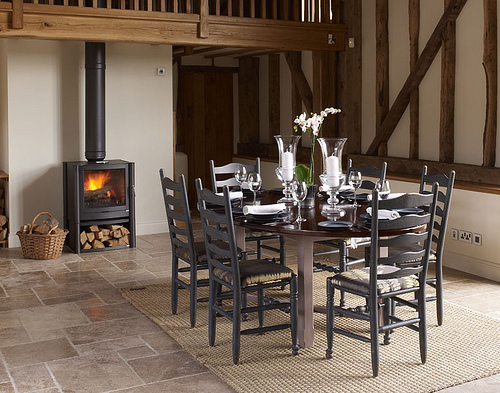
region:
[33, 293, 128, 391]
The floor is tiled.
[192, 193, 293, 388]
The chair is grey.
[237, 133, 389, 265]
The table is set.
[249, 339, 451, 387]
The rug is tan.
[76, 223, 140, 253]
The wood is under the fireplace.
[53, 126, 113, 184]
The fireplace is on.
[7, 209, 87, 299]
The basket is next to the fire place.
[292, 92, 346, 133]
The flower is white.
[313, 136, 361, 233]
The candle is white.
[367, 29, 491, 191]
The panels are white.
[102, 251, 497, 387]
Floor mate with dining room set setting on it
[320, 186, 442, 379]
Dark brown dining room chair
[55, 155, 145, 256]
Wood burning stove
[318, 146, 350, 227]
White candle in candle holder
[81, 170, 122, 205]
Fire in wood burning stove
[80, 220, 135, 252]
Chopped logs for wood burning stove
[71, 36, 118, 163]
Black wood stove pipe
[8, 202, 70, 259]
Basket with chopped logs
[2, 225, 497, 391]
Ceramic tiled floor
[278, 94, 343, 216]
White flowers in a vase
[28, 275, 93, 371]
this is the floor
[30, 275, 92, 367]
the floor is made of tiles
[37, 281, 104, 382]
the floor is slippery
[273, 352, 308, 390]
this is a carpet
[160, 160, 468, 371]
these are six chairs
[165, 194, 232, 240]
the chairs are wooden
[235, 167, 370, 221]
these are several champagne glases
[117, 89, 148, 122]
this is the wall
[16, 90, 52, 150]
the wall is white in color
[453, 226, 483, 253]
this is a socket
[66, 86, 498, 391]
a dinning room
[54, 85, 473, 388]
a dining room with fireplace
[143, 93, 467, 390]
a back chairs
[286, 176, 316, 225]
a wine glass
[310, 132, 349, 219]
a glass candle holder with candle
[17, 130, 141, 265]
a fireplace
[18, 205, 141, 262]
a pile of firewood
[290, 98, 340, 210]
an orchid as a center piece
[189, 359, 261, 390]
a rug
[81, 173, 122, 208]
a burning wood in the fireplace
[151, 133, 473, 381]
six chairs around a table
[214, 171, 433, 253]
table is brown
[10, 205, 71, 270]
a basket with logs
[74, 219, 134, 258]
logs under the fire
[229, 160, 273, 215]
two glasses on a table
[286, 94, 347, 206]
white flowers on a table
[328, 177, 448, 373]
chair is color gray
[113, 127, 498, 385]
a table under a brown rug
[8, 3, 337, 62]
a balcony over a fireplace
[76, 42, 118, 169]
a exhaust pipe in a room